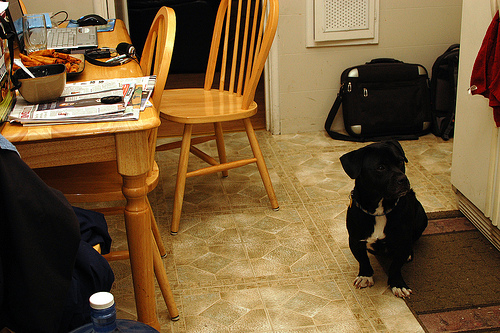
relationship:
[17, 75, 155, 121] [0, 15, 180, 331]
magazines on table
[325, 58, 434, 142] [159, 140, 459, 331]
bag on floor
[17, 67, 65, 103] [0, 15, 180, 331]
bowl on table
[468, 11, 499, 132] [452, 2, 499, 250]
clothing on wall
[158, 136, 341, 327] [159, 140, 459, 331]
tiles on floor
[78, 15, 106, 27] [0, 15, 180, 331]
mouse on table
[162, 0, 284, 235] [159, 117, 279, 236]
chair has legs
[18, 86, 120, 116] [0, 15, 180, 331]
newspaper on table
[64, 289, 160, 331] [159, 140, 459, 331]
jug on floor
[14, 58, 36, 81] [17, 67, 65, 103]
spoon in bowl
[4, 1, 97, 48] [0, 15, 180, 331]
laptop on table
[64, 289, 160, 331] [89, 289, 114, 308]
jug has lid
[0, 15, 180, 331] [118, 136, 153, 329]
table has leg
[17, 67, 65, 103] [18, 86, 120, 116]
bowl on top of newspaper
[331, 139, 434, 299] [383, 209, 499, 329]
dog on carpet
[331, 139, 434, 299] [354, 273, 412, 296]
dog has paws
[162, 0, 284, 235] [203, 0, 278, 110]
chair has back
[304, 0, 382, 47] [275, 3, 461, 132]
vent in wall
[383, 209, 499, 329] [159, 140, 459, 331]
mat on floor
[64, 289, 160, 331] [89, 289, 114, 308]
bottle has lid